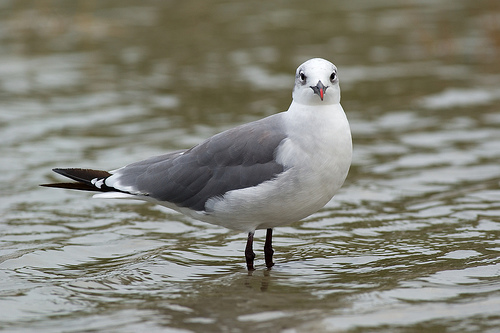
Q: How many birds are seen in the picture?
A: One.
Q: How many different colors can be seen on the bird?
A: 4.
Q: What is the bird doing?
A: Standing in water.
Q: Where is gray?
A: The wing.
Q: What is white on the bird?
A: Chest and belly.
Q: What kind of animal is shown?
A: A bird.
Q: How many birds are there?
A: 1.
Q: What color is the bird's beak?
A: Gray with red.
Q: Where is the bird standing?
A: In water.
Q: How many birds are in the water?
A: One.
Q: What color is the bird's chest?
A: White.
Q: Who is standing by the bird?
A: Nobody.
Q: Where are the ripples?
A: In the water.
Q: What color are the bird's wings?
A: Gray.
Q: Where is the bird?
A: In water.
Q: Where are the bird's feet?
A: Under water.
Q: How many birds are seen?
A: 1.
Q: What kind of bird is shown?
A: Seagull.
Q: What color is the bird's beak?
A: Orange.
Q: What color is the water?
A: Brown.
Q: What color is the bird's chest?
A: White.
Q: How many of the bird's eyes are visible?
A: 2.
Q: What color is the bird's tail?
A: Black.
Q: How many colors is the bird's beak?
A: 2.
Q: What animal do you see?
A: Bird.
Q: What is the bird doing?
A: Standing in water.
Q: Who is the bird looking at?
A: The photographer.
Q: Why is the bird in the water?
A: To catch fish.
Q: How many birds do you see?
A: One.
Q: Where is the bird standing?
A: In water.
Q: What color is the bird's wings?
A: Gray.